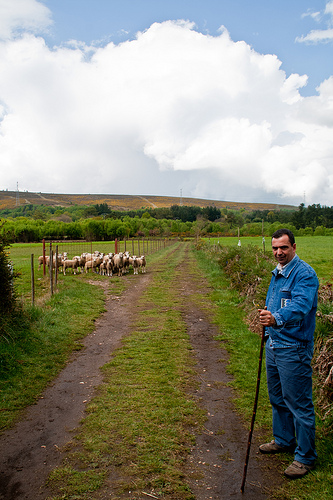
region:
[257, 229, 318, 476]
a man in a blue outfit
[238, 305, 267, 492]
a man's walking stick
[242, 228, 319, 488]
a man carrying a walking stick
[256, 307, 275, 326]
a man's left fist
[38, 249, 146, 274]
a herd of sheep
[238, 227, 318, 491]
a sheep herder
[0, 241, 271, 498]
a grassy dirt road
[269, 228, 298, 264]
a man's head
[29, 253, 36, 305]
a metal fence post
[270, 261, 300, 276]
a man's shirt collar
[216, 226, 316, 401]
man wearing blue and holding stick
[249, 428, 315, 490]
brown shoes on man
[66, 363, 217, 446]
green grass and brown dirt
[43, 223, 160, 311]
animals in the background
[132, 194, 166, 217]
walkway in the background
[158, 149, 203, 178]
white clouds in the sky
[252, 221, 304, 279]
man looking at camera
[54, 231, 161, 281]
many animals in a group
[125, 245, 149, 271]
white fur on animals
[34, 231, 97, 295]
fence next to animals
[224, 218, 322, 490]
A man in blue holding a large stick.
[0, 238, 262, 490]
a path with tracks for cars.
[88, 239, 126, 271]
An open gate.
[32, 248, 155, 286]
A group of animals going through the gate.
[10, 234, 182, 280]
A green grassy area.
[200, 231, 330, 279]
A green grassy area.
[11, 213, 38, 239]
A tree full of leaves.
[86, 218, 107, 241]
A tree full of leaves.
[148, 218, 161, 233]
A tree full of leaves.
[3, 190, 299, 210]
A far off hillside.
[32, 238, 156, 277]
A flock of sheep in the distance.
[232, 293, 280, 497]
The man is holding a stick.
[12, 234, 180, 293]
A fence is next to the dirt road.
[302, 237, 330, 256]
Grass is growing in the field.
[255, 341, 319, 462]
The man is wearing jeans.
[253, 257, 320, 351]
The man is wearing a jean jacket.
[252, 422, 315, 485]
The man has shoes on his feet.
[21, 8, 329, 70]
The sky is cloudy and blue.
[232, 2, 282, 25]
Part of the sky is blue.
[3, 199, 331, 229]
Trees are growing in the distance.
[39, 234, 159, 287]
A herd of sheep.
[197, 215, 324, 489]
The man is holding a walking stick.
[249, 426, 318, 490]
The shoes are brown.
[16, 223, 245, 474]
A path worn by tires from vehicles.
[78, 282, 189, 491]
Grass is in-between the areas worn by vehicle's tires.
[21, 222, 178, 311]
A long fence.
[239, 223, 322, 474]
The man is dressed in blue clothing.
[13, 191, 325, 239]
A forest.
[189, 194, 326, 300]
A field is behind the man.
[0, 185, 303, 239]
A large hill is behind the forest.